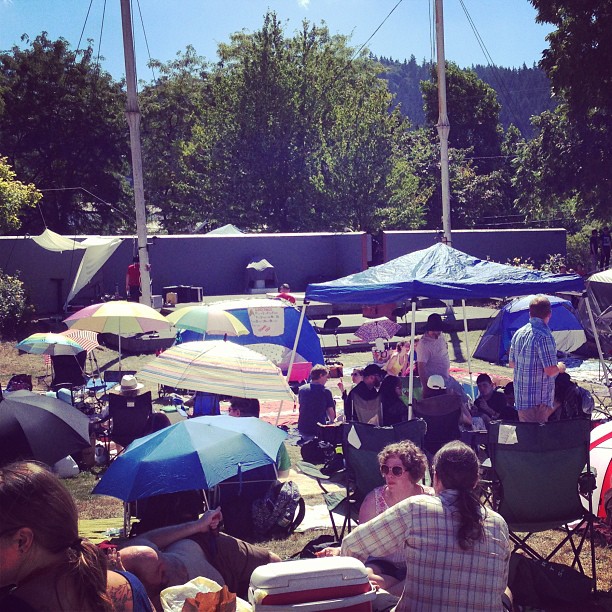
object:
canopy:
[275, 242, 612, 428]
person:
[120, 506, 283, 590]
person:
[0, 460, 154, 611]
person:
[359, 440, 435, 524]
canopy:
[305, 242, 584, 305]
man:
[340, 440, 511, 611]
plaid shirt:
[341, 489, 512, 610]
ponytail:
[457, 492, 488, 551]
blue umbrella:
[90, 415, 288, 503]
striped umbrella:
[134, 332, 298, 401]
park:
[0, 228, 611, 610]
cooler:
[248, 556, 377, 612]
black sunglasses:
[381, 465, 403, 478]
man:
[509, 295, 566, 422]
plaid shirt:
[509, 317, 558, 410]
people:
[298, 296, 566, 437]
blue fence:
[0, 227, 567, 315]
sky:
[357, 0, 527, 71]